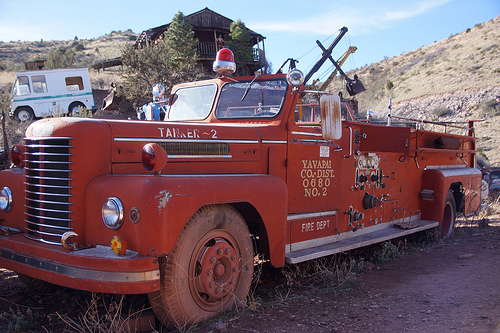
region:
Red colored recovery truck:
[1, 23, 497, 330]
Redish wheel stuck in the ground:
[145, 197, 265, 332]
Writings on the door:
[284, 81, 351, 247]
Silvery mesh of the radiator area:
[18, 130, 78, 252]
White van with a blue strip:
[5, 65, 96, 120]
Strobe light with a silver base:
[211, 43, 237, 74]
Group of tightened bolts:
[203, 243, 242, 301]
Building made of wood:
[128, 3, 266, 76]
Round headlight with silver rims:
[98, 195, 127, 230]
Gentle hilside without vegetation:
[318, 11, 498, 208]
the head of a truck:
[26, 115, 111, 257]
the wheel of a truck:
[186, 230, 247, 318]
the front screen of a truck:
[173, 91, 208, 118]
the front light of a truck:
[101, 202, 124, 226]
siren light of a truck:
[216, 45, 234, 76]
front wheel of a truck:
[179, 220, 256, 317]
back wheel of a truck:
[440, 194, 466, 243]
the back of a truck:
[292, 100, 497, 230]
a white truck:
[18, 76, 97, 106]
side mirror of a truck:
[317, 91, 345, 138]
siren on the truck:
[212, 49, 246, 71]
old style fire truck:
[1, 75, 495, 332]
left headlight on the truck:
[93, 181, 127, 228]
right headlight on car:
[1, 181, 16, 216]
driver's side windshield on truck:
[217, 79, 285, 121]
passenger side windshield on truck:
[168, 82, 212, 124]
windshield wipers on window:
[239, 75, 258, 101]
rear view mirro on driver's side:
[317, 91, 344, 154]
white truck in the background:
[7, 69, 96, 121]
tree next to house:
[167, 17, 195, 77]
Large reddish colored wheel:
[139, 199, 266, 331]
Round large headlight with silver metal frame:
[98, 195, 125, 230]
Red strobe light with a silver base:
[208, 45, 239, 77]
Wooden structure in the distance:
[93, 10, 274, 83]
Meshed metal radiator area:
[18, 133, 80, 254]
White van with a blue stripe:
[5, 63, 100, 123]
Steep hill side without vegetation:
[308, 11, 498, 208]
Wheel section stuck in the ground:
[146, 286, 281, 331]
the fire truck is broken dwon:
[40, 77, 476, 322]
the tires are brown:
[176, 225, 269, 321]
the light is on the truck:
[210, 46, 242, 71]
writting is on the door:
[300, 150, 349, 244]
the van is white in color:
[11, 61, 103, 128]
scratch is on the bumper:
[154, 183, 200, 220]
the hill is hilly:
[398, 32, 498, 120]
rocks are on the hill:
[419, 77, 493, 123]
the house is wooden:
[129, 13, 272, 63]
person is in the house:
[211, 27, 234, 47]